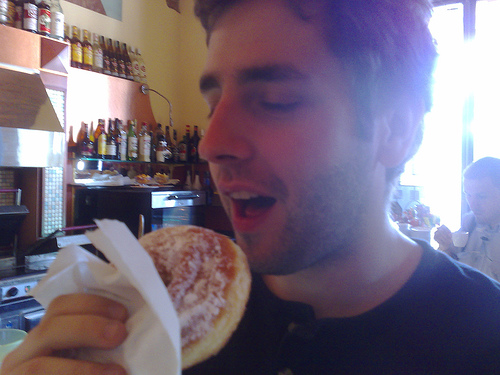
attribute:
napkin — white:
[28, 214, 184, 374]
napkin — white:
[59, 240, 161, 345]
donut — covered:
[129, 223, 251, 369]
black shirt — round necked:
[166, 235, 495, 374]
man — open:
[2, 3, 498, 373]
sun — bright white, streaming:
[398, 4, 498, 240]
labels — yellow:
[70, 39, 93, 65]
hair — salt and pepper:
[191, 6, 494, 193]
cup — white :
[76, 187, 233, 361]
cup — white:
[54, 8, 69, 38]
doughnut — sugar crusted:
[134, 224, 256, 373]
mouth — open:
[217, 178, 279, 230]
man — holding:
[214, 23, 499, 320]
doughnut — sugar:
[141, 204, 271, 361]